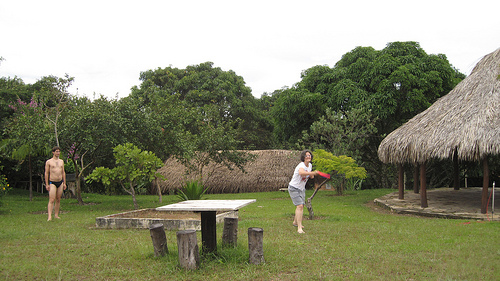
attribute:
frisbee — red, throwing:
[313, 161, 338, 177]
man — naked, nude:
[14, 138, 78, 250]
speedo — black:
[38, 175, 70, 195]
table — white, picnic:
[164, 186, 260, 223]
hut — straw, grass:
[424, 110, 474, 136]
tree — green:
[260, 94, 350, 139]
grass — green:
[119, 134, 162, 171]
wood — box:
[426, 168, 495, 201]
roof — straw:
[182, 139, 286, 200]